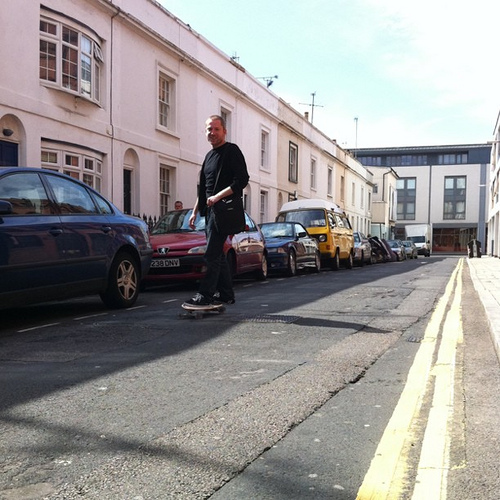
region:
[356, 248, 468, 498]
double yellow line down middle of road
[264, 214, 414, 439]
road with cars parked along the side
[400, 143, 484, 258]
white building with black top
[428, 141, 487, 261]
large white and black building with large window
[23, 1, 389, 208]
long white building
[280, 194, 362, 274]
yellow bus parked along side road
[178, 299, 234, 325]
white skateboard on road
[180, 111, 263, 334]
man standing on white skateboard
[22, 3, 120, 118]
bay window on white building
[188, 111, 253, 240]
balding man wearing black jacket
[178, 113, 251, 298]
man dressed in all black outfit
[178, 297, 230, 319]
skateboard man is riding down street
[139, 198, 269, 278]
red car parked on the street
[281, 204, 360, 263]
yellow van parked on street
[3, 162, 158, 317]
dark blue car parked on street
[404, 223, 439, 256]
white box truck parked on street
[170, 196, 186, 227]
man walking behind red car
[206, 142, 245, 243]
messenger bag of man on skateboard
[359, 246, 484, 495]
white line painted down the street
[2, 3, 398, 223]
pink building length of street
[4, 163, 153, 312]
This is a car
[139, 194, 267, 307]
This is a car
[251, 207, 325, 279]
This is a car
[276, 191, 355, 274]
This is a car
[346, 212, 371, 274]
This is a car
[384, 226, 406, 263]
This is a car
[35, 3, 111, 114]
This is a window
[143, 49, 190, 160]
This is a window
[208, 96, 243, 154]
This is a window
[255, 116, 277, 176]
This is a window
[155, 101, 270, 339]
The man is skateboarding.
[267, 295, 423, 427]
Cracks are in the road.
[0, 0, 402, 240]
A row of townhouses.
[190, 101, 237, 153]
The man is smiling.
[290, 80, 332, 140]
An antenna on the roof.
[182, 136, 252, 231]
The man is wearing a black jacket.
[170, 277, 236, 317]
Sneakers.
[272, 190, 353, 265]
A yellow and white van.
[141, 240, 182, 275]
A license plate.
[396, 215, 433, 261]
A white truck.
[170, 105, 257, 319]
man on a skateboard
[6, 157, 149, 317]
blue car parked on road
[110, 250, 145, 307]
black tire of blue car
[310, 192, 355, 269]
yellow van with white top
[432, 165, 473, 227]
windows of white building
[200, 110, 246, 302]
man wearing black clothes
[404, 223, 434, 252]
white truck parked on road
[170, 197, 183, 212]
head of man behind car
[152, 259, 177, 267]
license plate of red car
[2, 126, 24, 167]
door of pink building